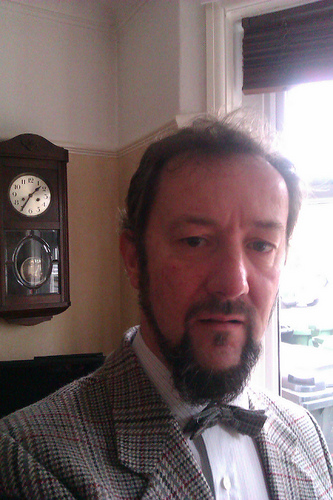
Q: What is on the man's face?
A: Beard.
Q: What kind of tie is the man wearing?
A: Bow.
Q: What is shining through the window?
A: Sun.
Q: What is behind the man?
A: Clock.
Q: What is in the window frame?
A: Blinds.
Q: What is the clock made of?
A: Wood.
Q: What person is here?
A: A guy.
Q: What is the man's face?
A: Side burns.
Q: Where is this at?
A: A living room.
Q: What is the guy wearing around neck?
A: Bow tie.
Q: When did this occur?
A: During the day time.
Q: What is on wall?
A: Clock.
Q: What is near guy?
A: Window.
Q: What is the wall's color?
A: White.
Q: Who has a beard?
A: The man.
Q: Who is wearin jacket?
A: The man.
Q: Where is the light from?
A: Window.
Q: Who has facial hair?
A: The man.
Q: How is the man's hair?
A: Short.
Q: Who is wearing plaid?
A: The man.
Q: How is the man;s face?
A: Hairy.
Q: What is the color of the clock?
A: Brown.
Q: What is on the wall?
A: A clock.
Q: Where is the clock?
A: On the wall.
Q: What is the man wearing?
A: A suit and tie.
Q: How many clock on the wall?
A: One.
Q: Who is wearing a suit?
A: A man.